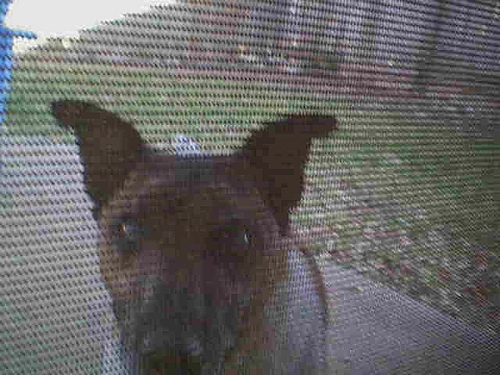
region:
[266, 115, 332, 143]
ear of the dog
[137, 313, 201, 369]
nose of the dog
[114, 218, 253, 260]
eyes of the dog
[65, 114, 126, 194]
ear of the dog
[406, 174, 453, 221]
pattern on the door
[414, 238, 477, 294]
leaves on the grass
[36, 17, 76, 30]
light on the fence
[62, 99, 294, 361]
head of the dog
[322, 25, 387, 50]
fence in the back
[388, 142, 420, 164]
parts of the grass are greener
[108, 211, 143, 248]
The dogs right eye is black.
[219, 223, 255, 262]
The dogs left eye is black.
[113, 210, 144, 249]
The dogs right eye is round.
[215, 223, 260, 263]
The dogs left eye is round.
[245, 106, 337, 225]
The dogs left ear is black.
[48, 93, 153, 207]
The dogs right eye is black.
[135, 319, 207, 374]
The dogs nose is black.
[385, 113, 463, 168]
The grass is green.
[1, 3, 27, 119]
The object in the background is blue.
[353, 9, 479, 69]
The fence in the background is brown.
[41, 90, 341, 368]
dog behind the fence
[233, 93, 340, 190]
ear of the dog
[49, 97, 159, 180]
ear of the dog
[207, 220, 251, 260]
eye of the dog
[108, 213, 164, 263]
eye of the dog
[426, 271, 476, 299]
leaves on the ground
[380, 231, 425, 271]
leaves on the ground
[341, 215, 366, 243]
leaves on the ground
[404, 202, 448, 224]
leaves on the ground